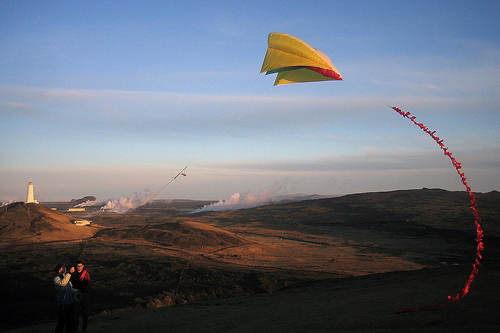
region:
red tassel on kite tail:
[405, 109, 411, 116]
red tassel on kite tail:
[407, 115, 416, 122]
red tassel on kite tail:
[416, 122, 421, 130]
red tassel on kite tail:
[428, 129, 436, 136]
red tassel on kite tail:
[436, 138, 443, 144]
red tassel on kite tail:
[455, 167, 466, 179]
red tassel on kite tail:
[444, 295, 451, 300]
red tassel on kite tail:
[473, 256, 480, 263]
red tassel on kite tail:
[475, 249, 483, 259]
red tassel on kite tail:
[469, 261, 479, 273]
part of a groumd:
[297, 235, 322, 268]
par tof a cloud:
[276, 158, 306, 198]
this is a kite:
[270, 42, 342, 104]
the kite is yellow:
[275, 25, 345, 175]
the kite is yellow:
[253, 39, 313, 101]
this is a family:
[29, 212, 118, 324]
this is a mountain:
[355, 188, 434, 268]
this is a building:
[4, 157, 74, 237]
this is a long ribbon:
[369, 86, 474, 256]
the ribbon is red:
[437, 209, 472, 267]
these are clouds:
[105, 88, 162, 158]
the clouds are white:
[264, 156, 313, 229]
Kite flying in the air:
[252, 27, 496, 231]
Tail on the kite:
[385, 98, 497, 220]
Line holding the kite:
[124, 172, 224, 308]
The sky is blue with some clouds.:
[24, 12, 280, 180]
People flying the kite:
[35, 250, 111, 317]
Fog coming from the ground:
[207, 163, 339, 197]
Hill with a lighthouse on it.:
[9, 169, 61, 224]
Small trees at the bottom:
[122, 269, 347, 289]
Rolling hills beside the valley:
[122, 210, 342, 277]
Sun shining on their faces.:
[43, 248, 103, 318]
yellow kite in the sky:
[257, 29, 348, 94]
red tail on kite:
[398, 103, 498, 212]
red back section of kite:
[306, 63, 336, 83]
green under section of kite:
[262, 66, 297, 85]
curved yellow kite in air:
[245, 35, 342, 96]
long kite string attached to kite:
[138, 102, 252, 204]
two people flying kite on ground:
[42, 255, 89, 305]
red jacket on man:
[75, 272, 93, 283]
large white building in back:
[20, 176, 34, 208]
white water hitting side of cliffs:
[203, 179, 290, 214]